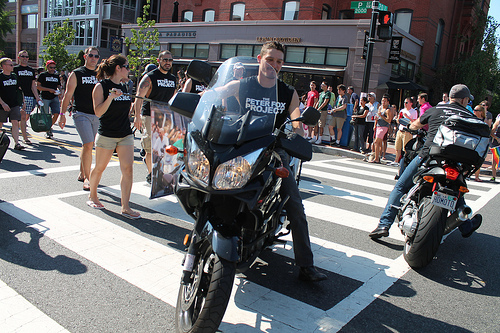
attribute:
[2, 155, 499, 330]
crosswalk — painted , white 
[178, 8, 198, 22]
window — small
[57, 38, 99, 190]
person — walking 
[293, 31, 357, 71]
window — small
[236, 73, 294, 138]
shirt — black, white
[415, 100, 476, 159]
shirt — white, black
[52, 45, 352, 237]
people — group 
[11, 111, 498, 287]
street — city 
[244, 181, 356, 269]
jeans — blue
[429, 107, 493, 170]
bag — black, white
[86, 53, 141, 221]
pedestrian — signal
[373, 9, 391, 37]
signal — do not walk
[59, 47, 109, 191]
pedestrian — signal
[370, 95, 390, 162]
pedestrian — signal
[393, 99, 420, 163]
pedestrian — signal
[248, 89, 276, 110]
shirt — Peter Fox Project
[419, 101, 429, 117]
shirt — pink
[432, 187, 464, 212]
plate — license 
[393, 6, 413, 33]
window — small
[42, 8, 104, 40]
windows — glass 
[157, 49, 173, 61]
hair — brown